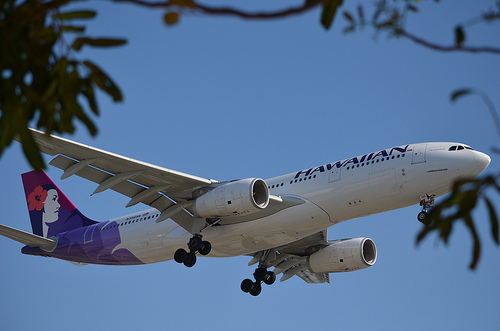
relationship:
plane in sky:
[1, 117, 492, 297] [1, 1, 497, 327]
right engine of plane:
[180, 174, 282, 221] [1, 117, 492, 297]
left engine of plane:
[303, 238, 383, 278] [1, 117, 492, 297]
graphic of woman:
[11, 163, 144, 275] [26, 182, 63, 239]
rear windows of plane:
[94, 213, 163, 232] [1, 117, 492, 297]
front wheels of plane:
[410, 190, 441, 227] [1, 117, 492, 297]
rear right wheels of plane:
[168, 233, 218, 269] [1, 117, 492, 297]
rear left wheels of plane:
[237, 266, 278, 297] [1, 117, 492, 297]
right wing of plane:
[14, 123, 217, 236] [1, 117, 492, 297]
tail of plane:
[16, 166, 101, 240] [1, 117, 492, 297]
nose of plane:
[470, 151, 493, 179] [1, 117, 492, 297]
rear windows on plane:
[94, 213, 163, 232] [1, 117, 492, 297]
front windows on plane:
[269, 153, 410, 189] [1, 117, 492, 297]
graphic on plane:
[11, 163, 144, 275] [1, 117, 492, 297]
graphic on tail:
[11, 163, 144, 275] [16, 166, 101, 240]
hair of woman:
[28, 182, 58, 239] [26, 182, 63, 239]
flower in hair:
[27, 183, 49, 209] [28, 182, 58, 239]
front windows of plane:
[269, 153, 410, 189] [1, 117, 492, 297]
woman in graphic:
[26, 182, 63, 239] [11, 163, 144, 275]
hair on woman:
[28, 182, 58, 239] [26, 182, 63, 239]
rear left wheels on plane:
[237, 266, 278, 297] [1, 117, 492, 297]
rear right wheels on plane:
[168, 233, 218, 269] [1, 117, 492, 297]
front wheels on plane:
[410, 190, 441, 227] [1, 117, 492, 297]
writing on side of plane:
[292, 144, 410, 177] [1, 117, 492, 297]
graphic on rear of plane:
[11, 163, 144, 275] [1, 117, 492, 297]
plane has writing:
[1, 117, 492, 297] [292, 144, 410, 177]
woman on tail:
[26, 182, 63, 239] [16, 166, 101, 240]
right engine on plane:
[180, 174, 282, 221] [1, 117, 492, 297]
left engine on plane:
[303, 238, 383, 278] [1, 117, 492, 297]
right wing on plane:
[14, 123, 217, 236] [1, 117, 492, 297]